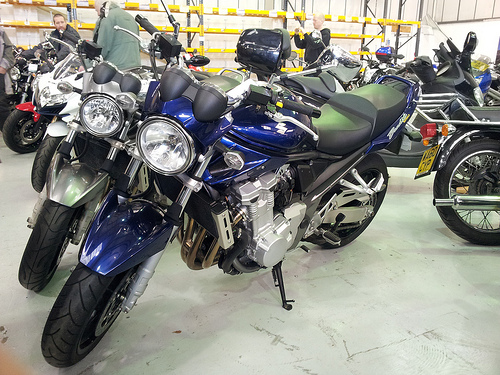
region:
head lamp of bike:
[136, 115, 201, 177]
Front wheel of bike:
[33, 200, 182, 368]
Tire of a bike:
[12, 165, 74, 283]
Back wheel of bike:
[314, 149, 389, 244]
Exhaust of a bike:
[429, 196, 498, 212]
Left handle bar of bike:
[228, 79, 329, 146]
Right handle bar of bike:
[135, 10, 191, 67]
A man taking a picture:
[285, 5, 342, 62]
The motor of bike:
[202, 155, 317, 271]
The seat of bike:
[298, 89, 374, 143]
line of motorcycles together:
[16, 34, 429, 314]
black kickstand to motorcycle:
[252, 276, 299, 321]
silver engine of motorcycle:
[223, 169, 313, 262]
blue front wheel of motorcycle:
[66, 195, 164, 277]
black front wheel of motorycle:
[33, 265, 101, 365]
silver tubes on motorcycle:
[181, 223, 224, 271]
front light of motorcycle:
[134, 98, 196, 184]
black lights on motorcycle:
[166, 71, 221, 121]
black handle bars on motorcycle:
[278, 90, 321, 120]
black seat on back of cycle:
[308, 88, 391, 139]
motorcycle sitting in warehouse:
[138, 41, 415, 271]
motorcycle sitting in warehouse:
[80, 59, 127, 140]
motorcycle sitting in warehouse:
[41, 61, 67, 146]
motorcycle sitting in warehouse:
[3, 49, 42, 158]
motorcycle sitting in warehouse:
[430, 103, 499, 213]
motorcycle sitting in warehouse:
[394, 37, 490, 108]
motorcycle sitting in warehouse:
[319, 45, 351, 99]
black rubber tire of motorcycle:
[40, 259, 165, 344]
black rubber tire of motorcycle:
[435, 134, 495, 216]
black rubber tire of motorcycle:
[27, 216, 69, 273]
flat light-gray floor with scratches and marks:
[0, 122, 495, 369]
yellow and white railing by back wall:
[2, 1, 417, 72]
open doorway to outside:
[420, 1, 495, 66]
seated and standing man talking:
[40, 0, 140, 65]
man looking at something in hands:
[280, 10, 330, 65]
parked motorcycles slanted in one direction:
[20, 15, 421, 355]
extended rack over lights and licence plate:
[411, 85, 491, 251]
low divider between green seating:
[315, 80, 410, 155]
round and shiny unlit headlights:
[75, 86, 192, 171]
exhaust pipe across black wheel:
[431, 145, 496, 245]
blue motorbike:
[50, 64, 400, 358]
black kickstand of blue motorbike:
[272, 263, 297, 310]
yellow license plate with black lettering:
[410, 143, 436, 176]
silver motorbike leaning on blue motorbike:
[21, 65, 156, 264]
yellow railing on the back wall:
[8, 0, 429, 105]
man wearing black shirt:
[283, 16, 340, 74]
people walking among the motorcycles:
[48, 5, 365, 88]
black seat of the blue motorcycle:
[298, 78, 405, 153]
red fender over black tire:
[11, 91, 40, 117]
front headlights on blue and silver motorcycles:
[78, 100, 198, 173]